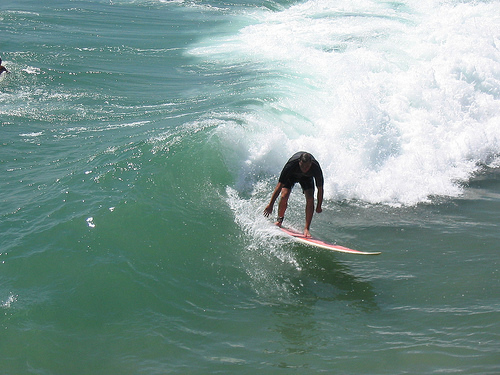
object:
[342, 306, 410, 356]
ripples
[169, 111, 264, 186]
wave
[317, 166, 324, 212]
arm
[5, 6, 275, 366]
watter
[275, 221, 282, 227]
foot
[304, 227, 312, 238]
foot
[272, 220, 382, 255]
board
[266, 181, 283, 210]
arm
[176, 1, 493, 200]
wave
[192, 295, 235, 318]
ripples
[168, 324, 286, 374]
ripples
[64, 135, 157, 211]
ripples water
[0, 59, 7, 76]
person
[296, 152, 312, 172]
head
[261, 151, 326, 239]
man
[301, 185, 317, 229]
leg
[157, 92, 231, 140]
ripples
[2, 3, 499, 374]
water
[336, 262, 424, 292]
ripples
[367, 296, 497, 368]
ripples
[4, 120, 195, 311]
ripples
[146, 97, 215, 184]
ripples water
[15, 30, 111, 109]
ripples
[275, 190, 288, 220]
leg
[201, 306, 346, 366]
small ripples